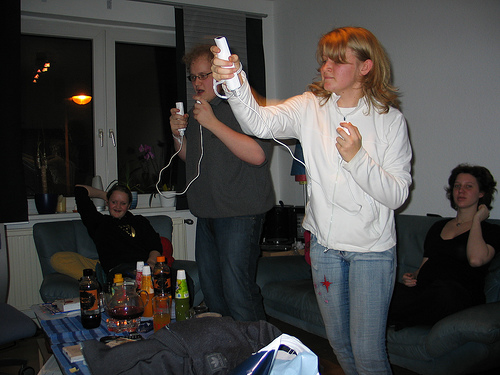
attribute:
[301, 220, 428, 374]
jeans — faded